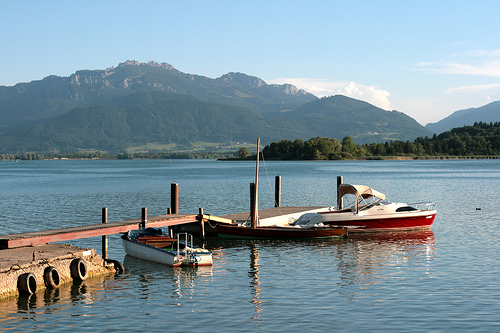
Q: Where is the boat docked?
A: Pier.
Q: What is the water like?
A: Calm.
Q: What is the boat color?
A: Red.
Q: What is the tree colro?
A: Green.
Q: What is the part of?
A: Boat.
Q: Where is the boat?
A: On the water.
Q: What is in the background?
A: Mountains.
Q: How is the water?
A: Calm.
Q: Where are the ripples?
A: On the water.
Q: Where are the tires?
A: On the dock.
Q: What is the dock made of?
A: Wood.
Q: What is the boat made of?
A: Fiberglass.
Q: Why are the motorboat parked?
A: They are not in use.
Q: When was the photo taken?
A: Daytime.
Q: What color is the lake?
A: Blue.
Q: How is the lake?
A: Calm.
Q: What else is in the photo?
A: Mountains.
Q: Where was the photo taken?
A: At a dock.